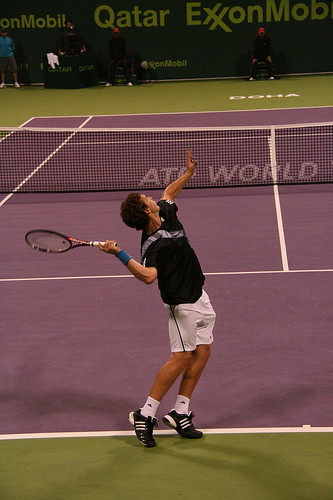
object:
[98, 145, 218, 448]
player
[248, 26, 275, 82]
judge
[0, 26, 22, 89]
man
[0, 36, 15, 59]
t-shirt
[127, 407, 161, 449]
sneakers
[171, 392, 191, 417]
socks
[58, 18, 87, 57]
camera man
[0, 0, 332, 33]
sign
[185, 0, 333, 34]
exxon mobile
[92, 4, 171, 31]
qatar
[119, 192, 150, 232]
hair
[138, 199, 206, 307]
shirt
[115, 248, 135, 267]
wrist band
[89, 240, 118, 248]
grip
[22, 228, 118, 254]
racket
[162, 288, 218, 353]
pants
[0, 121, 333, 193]
net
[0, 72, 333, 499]
court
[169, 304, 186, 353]
stripe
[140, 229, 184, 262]
accent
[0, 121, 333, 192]
across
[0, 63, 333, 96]
at end court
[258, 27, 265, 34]
cap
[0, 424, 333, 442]
line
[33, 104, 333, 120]
line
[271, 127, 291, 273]
line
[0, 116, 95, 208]
line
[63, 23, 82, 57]
camera